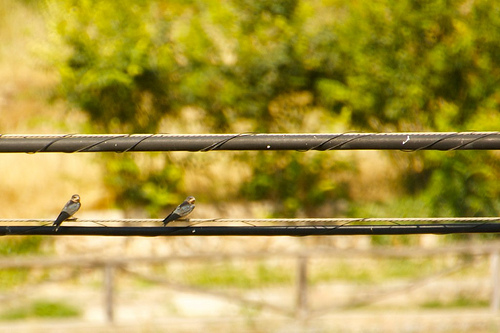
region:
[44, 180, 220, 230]
birds on the wire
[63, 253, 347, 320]
the ground is blurry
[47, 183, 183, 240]
the birds are sitting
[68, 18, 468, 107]
the trees are blurred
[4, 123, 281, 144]
the pole is metal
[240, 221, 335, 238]
the wire is black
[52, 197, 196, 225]
the birds are small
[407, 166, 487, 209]
the leaves are blurry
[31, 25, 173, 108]
the trees are blurred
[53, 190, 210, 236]
Bird sitting on a wire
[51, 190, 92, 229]
Bird sitting on a wire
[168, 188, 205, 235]
Bird sitting on a wire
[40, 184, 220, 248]
Bird sitting on a wire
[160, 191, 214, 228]
Bird sitting on a wire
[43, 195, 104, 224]
Bird sitting on a wire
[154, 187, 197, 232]
Bird sitting on a wire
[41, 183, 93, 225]
Bird sitting on a wire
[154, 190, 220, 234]
Bird sitting on a wire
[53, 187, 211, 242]
two birds sitting on wire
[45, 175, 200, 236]
two birds sitting on wire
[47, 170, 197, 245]
two birds sitting on wire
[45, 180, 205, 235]
two birds sitting on wire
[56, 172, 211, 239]
two birds sitting on wire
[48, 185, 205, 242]
two birds sitting on wire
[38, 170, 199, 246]
two birds sitting on wire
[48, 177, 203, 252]
two birds sitting on wire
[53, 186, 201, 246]
two birds sitting on wire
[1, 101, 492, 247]
birds sitting on a black wire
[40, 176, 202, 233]
two birds perched on lower wire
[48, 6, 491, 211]
trees behind the wires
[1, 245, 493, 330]
railing with posts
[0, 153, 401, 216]
patch of dry grass in between the shrubs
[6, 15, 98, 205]
a patch of dry grass to the left of the shrubs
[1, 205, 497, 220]
a rope made of natural fibers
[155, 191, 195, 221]
bird has black and grey feathers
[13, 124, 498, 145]
a thick black wire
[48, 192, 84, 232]
Bird perched on a cable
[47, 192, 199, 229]
Birds perched on a cable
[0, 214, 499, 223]
Line of grey cable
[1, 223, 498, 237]
Line of black cable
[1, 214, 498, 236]
Couple of different sized cables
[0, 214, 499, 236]
Cables of different colors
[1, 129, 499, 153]
Large black colored cable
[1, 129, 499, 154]
Thin black cable coiled along the length of a larger one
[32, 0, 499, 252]
Green vegetation in the background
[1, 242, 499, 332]
Low fence with a woodentop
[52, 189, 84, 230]
bird on the wire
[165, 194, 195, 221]
bird on the wire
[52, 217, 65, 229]
tail of a bird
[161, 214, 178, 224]
tail of a bird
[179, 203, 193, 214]
wing of a bird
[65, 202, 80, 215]
wing of a bird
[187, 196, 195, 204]
head of a bird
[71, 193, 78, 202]
head of a bird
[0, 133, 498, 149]
the cable is steel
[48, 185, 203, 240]
A couple of black birds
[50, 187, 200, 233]
A couple of black birds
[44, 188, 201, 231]
A couple of black birds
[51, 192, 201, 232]
A couple of black birds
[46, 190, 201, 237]
A couple of black birds